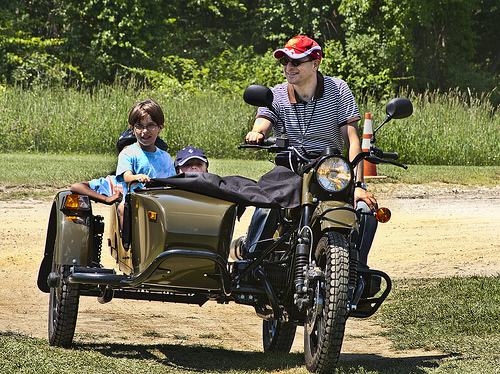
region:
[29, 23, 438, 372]
a motorcycle with a sidecar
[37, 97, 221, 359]
three children in a sidecar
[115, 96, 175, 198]
a boy with glasses and blue shirt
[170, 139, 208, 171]
a blue cap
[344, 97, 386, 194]
an orange and white traffic cone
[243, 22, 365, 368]
a smiling man with a striped shirt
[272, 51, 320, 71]
black sunglasses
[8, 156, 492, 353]
a dirt road lined by grass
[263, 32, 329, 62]
a red yellow and white cap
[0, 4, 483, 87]
trees alongside road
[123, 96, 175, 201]
young boy in blue tee shirt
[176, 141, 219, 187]
top of child's head with hat on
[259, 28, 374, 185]
man wearing a red hat on head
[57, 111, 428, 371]
vintage motorcycle with sidecar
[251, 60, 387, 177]
black and white striped polo shirt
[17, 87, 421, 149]
tall green grass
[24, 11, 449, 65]
trees with green leaves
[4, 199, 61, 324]
dirt path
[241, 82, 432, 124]
black side mirrors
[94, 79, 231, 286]
children riding in sidecar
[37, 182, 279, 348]
side car of motorcycle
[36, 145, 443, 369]
brown motorcycle and side car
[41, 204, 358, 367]
three black motorcycle tires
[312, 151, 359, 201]
headlight on front of motorcycle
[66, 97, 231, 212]
children enjoying ride in sidecar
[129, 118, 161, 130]
glasses on boys face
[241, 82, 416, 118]
black side view mirrors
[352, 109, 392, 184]
traffic cone on side of road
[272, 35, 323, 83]
man's head with sunglasses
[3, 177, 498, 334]
dirt track for riding off road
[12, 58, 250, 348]
Three kids sitting in the side car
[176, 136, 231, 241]
Child wearing a cap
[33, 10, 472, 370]
Gold motorcycle with side car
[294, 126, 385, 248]
Headlight on front of bike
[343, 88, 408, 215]
Safety cone in background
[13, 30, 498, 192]
Tall grass in the distance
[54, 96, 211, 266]
Boy sitting on top of the other boy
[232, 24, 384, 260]
Cool biker polo shirt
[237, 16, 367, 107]
Wearing shades and a red cap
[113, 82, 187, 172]
Boy wearing glasses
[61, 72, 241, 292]
kids in the bucket of a motorcycle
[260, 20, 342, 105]
man with red hat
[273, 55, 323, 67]
sunglasses on man's face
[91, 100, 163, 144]
glasses on boys face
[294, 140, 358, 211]
motorcycle headlight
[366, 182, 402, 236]
an orange light on the motorcycle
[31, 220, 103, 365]
a skinny wheel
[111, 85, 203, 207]
a boy wearing a blue shirt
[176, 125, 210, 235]
a kid wearing a blue hat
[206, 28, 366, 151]
a man smiling